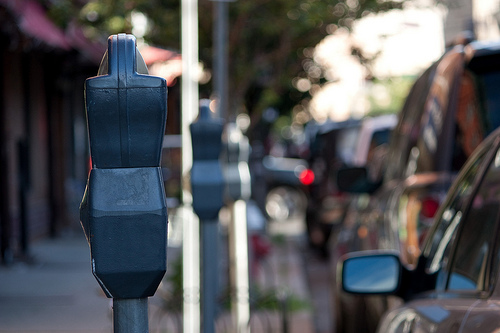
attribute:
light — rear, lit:
[281, 160, 323, 189]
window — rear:
[450, 149, 497, 300]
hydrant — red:
[236, 200, 269, 291]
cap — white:
[242, 198, 266, 233]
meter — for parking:
[89, 37, 171, 293]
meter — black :
[78, 32, 168, 332]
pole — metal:
[103, 291, 158, 329]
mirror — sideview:
[336, 249, 403, 299]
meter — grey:
[66, 32, 194, 299]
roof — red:
[6, 9, 102, 59]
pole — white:
[172, 4, 204, 331]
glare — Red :
[291, 166, 320, 185]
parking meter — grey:
[184, 95, 228, 227]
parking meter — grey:
[78, 37, 169, 300]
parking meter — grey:
[223, 119, 250, 198]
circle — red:
[300, 169, 314, 185]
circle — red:
[419, 198, 439, 218]